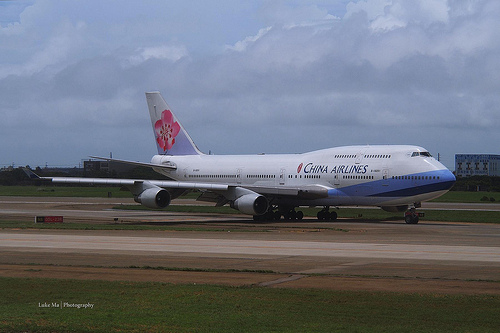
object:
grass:
[0, 274, 499, 332]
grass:
[112, 203, 499, 223]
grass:
[0, 218, 266, 233]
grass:
[0, 185, 499, 203]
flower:
[153, 107, 180, 156]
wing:
[17, 166, 335, 217]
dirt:
[0, 245, 498, 296]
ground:
[0, 184, 498, 331]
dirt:
[0, 213, 499, 247]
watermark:
[35, 300, 97, 311]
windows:
[408, 152, 416, 158]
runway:
[0, 226, 499, 294]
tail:
[140, 90, 204, 157]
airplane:
[20, 90, 457, 225]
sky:
[0, 0, 499, 177]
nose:
[435, 166, 458, 194]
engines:
[130, 187, 173, 210]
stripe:
[324, 168, 458, 196]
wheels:
[293, 208, 305, 222]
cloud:
[0, 0, 499, 167]